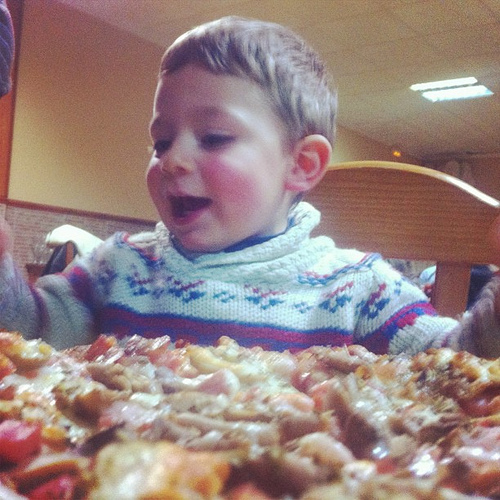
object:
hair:
[157, 15, 338, 217]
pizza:
[0, 328, 499, 499]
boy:
[0, 15, 499, 358]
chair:
[301, 158, 499, 317]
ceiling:
[54, 0, 499, 162]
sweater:
[0, 201, 499, 359]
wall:
[0, 0, 168, 288]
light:
[406, 73, 493, 104]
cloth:
[44, 223, 104, 258]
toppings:
[0, 332, 499, 499]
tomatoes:
[0, 418, 40, 465]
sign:
[440, 158, 462, 180]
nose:
[158, 128, 196, 177]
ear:
[284, 134, 332, 196]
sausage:
[245, 454, 300, 496]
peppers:
[417, 368, 466, 406]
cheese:
[121, 384, 165, 411]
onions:
[101, 402, 165, 430]